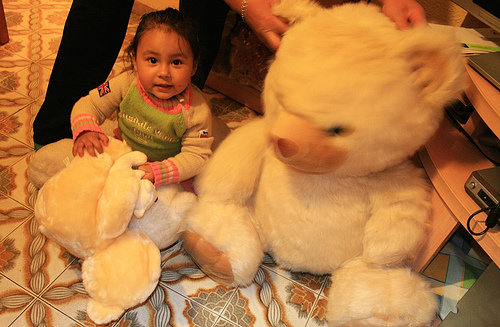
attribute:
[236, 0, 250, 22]
bracelet —  person's,  wrist's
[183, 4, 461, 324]
teddy — big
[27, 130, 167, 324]
bear — yellowish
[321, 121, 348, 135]
eye — black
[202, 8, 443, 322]
animal — big, stuffed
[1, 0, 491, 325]
floor — patterned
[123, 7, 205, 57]
hair — black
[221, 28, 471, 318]
bear — blurry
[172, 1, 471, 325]
teddy bear — big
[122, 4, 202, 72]
hair — black, girl's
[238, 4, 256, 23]
bracelet —  person's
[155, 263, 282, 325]
tile —  floor,  with design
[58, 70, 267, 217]
sweater — green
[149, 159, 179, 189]
stripes — pink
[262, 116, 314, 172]
nose — tan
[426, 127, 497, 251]
shelf — wood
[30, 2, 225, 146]
pants — black